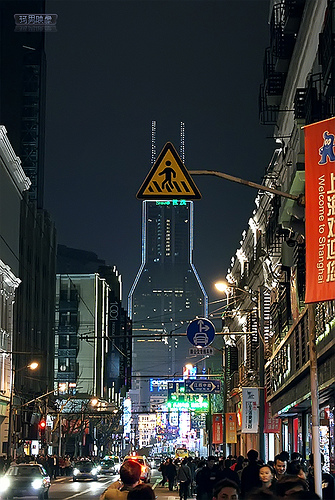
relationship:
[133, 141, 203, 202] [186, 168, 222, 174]
sign on pole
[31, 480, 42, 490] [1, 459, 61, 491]
headlight of car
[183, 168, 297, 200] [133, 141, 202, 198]
pole with sign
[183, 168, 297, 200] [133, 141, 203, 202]
pole in sign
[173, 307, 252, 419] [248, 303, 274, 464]
sign in pole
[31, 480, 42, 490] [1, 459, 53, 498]
headlight on car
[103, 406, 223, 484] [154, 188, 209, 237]
car has lights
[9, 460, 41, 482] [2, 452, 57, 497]
windshield on car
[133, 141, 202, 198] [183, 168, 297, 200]
sign on pole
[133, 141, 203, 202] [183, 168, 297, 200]
sign on pole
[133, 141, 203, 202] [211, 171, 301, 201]
sign on metal pole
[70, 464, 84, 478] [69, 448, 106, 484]
headlight on car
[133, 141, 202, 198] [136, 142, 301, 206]
sign on pole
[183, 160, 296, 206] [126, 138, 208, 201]
pole has sign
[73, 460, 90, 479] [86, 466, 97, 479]
car has headlight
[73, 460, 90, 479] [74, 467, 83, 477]
car has headlight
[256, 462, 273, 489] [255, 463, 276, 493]
head of person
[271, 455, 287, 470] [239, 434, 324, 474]
head of person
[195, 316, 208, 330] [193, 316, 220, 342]
arrows on sign